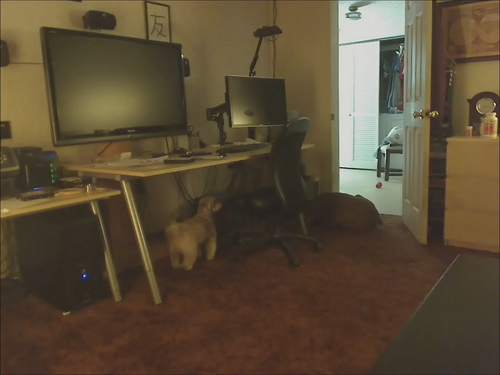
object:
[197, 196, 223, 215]
head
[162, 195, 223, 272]
dog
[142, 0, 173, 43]
symbol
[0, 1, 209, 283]
wall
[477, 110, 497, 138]
bottle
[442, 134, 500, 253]
dresser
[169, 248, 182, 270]
leg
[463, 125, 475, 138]
bottle